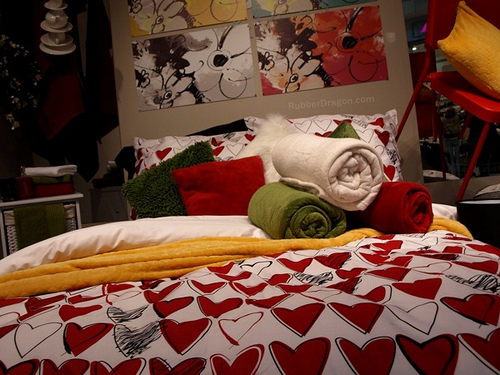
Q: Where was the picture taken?
A: A bedroom.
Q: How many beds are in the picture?
A: One.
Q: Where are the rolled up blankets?
A: On the bed.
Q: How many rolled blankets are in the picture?
A: Three.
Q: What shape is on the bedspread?
A: Hearts.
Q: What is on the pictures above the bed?
A: Flowers.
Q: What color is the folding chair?
A: Red.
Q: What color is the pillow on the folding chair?
A: Yellow.